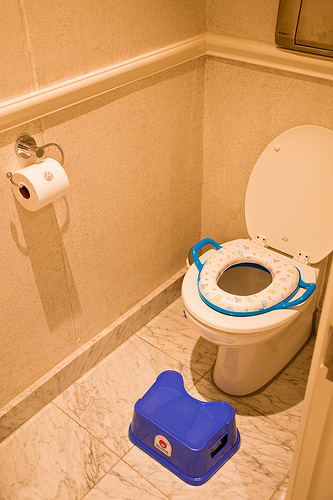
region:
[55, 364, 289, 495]
A white and black tile floor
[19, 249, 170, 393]
White and black tile molding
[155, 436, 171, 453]
red and white sticker on blue step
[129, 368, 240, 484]
Blue childs potty step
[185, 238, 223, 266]
The handle on the potty seat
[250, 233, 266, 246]
The hinge on the toilet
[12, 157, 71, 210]
A roll of toilet paper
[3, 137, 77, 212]
The toilet paper roll holder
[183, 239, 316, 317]
A child's toilet seat booster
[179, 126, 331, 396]
A white porcleain toilet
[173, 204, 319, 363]
multi-print cushion on toilet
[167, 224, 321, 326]
cushion has blue handles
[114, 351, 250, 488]
step stool in front of toilet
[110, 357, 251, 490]
step stool is blue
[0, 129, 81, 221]
toilet paper holder is silver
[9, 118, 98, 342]
toilet paper and holder casting shadow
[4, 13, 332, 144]
wall has white trim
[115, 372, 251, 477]
step stool has white emblem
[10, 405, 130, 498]
floor tile is white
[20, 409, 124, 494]
tile has marble design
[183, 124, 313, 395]
White tank-less porcelain toilet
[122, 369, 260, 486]
Toddler toilet training step in blue plastic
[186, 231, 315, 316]
Toddler toilet training seat on regular toilet seat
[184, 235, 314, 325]
Toilet training seat with blue plastic base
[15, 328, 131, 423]
White and gray grained marble base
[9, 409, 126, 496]
White and gray marble tiled floor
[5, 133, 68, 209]
Chrome toilet paper holder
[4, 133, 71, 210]
Single hook toilet paper holder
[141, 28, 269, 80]
Wooden white painted chair rail molding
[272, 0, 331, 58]
Stainless steel toilet seat protector holder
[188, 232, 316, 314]
a child's toilet seat with handles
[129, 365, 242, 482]
a blue child's step stool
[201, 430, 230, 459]
handle on a stepstool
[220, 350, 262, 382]
reflection in the white porcelain of a toilet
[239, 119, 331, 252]
a white toilet seat lid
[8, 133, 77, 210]
a roll of toilet paper on a dispenser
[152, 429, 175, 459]
a sticker on a stepstool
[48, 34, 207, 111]
white molding on a wall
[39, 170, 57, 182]
a logo on a roll of toilet paper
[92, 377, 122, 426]
a marble tile on the floor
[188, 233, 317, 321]
Toddler toilet seat on regular toilet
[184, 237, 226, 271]
Plastic handle of toddler toilet seat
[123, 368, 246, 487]
Plastic step stool for toddler use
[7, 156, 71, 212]
Roll of toilet tissue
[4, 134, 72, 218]
Toilet tissue on metal dispenser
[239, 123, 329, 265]
Open toilet seat lid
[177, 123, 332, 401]
Toilet with toddler seat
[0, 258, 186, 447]
Marble moulding along bathroom wall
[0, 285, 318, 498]
Square tiles on bathroom floor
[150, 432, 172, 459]
Manufacturer label on toddler step stool